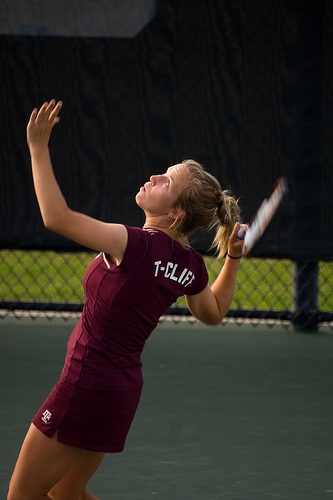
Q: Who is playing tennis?
A: A women.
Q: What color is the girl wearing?
A: Burgundy.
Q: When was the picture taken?
A: During the day.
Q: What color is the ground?
A: Green.